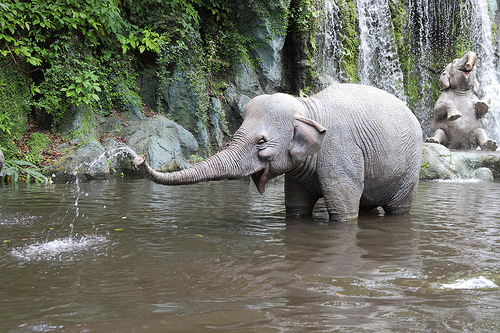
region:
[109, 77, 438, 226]
the elephant is n the water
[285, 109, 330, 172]
the elephant has an ear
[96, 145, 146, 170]
water is spouting fro the nose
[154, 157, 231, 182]
the elephant has a trunk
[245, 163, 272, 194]
the elephant has an open mouth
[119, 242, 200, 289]
the water is brown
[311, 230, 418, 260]
the water is deep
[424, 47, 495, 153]
the elephant is sitting up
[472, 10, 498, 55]
the water is white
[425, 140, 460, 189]
the boulder is gray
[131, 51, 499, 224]
grey elephants in water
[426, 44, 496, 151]
elephant playing in waterfall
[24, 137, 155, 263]
elephant shooting water out of her trunk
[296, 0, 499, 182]
waterfall is green and full of rock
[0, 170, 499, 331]
water is brown and rippled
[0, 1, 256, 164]
leaves are green and hanging down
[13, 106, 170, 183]
brown leaves on rocks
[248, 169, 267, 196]
elephant mouth is open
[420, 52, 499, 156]
elephant is sitting on butt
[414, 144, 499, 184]
large rocks in water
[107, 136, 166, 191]
The elephant is squirting water.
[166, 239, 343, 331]
The water is brown.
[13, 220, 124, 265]
White in the water.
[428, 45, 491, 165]
Elephant in the background.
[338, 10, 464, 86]
Grass growing on the side of the cliff.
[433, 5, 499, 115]
Waterfall behind the elephant.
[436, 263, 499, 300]
White spot in the water.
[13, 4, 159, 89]
The leaves are green.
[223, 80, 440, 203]
The elephant is grey.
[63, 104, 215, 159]
The rock is bluish grey.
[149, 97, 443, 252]
A baby elephant in the water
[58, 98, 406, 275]
A baby elephant spraying water out of its trunk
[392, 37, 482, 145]
A baby elephant sitting under a waterfall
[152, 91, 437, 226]
A grey baby elephant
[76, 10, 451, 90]
A riverbank with foilage on it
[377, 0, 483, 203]
A waterfall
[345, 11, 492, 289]
Water from a waterfall running into a large stream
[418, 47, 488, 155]
Baby elephant is sitting with its trunk raised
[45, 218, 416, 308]
Brown water in the stream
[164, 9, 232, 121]
Plants growing on the rocks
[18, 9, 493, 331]
a small waterfall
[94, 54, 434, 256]
an elephant playing in water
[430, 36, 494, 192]
elephant sitting upright on its tail bone next to a waterfall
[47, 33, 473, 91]
plants growing on the side of a waterfall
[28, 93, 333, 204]
elephant squirting water from its trunk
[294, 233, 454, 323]
ripples in a small body of water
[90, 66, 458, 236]
a happy looking elephant in water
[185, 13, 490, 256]
two elephants playing in a waterfall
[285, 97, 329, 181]
left ear of an elephant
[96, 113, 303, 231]
trunk of an elephant